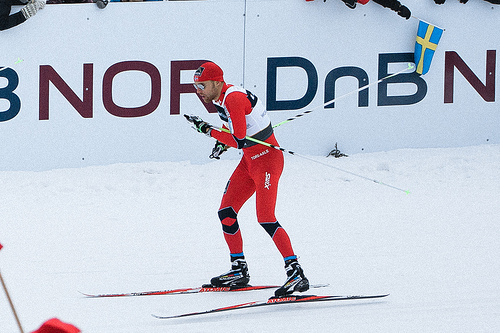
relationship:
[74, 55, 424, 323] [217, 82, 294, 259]
skier in snowsuit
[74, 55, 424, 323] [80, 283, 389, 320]
skier on skis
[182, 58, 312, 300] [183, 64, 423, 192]
man holding sticks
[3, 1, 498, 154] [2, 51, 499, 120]
wall has letters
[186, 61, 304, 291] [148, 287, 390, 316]
man on ski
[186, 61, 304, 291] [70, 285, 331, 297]
man on ski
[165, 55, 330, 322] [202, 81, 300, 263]
skier wearing outfit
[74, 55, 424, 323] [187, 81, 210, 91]
skier wearing sunglasses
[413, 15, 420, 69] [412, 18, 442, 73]
edge on flag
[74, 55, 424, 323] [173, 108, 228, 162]
skier wearing gloves